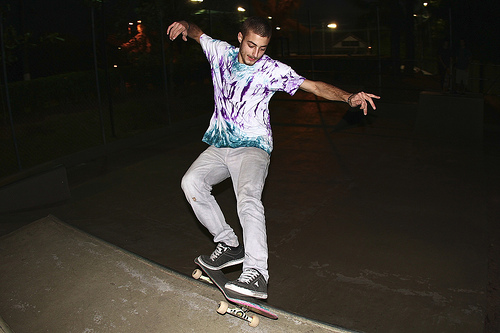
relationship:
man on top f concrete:
[163, 12, 381, 301] [7, 210, 334, 330]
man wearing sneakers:
[163, 12, 381, 301] [200, 239, 271, 300]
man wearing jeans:
[163, 12, 381, 301] [182, 144, 271, 274]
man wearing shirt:
[163, 12, 381, 301] [195, 31, 304, 152]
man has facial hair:
[163, 12, 381, 301] [241, 52, 258, 66]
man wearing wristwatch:
[163, 12, 381, 301] [345, 93, 355, 104]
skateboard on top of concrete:
[191, 255, 277, 324] [7, 210, 334, 330]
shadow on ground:
[104, 146, 151, 199] [76, 64, 496, 331]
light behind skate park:
[328, 21, 337, 28] [66, 0, 455, 321]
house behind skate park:
[331, 31, 370, 60] [66, 0, 455, 321]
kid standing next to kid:
[436, 36, 451, 86] [453, 35, 471, 85]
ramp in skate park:
[415, 90, 481, 144] [66, 0, 455, 321]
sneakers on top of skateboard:
[200, 239, 271, 300] [191, 255, 277, 324]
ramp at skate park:
[415, 90, 481, 144] [66, 0, 455, 321]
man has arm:
[163, 12, 381, 301] [301, 79, 379, 116]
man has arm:
[163, 12, 381, 301] [167, 21, 200, 42]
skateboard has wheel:
[191, 255, 277, 324] [191, 267, 199, 279]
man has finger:
[163, 12, 381, 301] [366, 92, 380, 100]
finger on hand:
[366, 92, 380, 100] [350, 90, 381, 113]